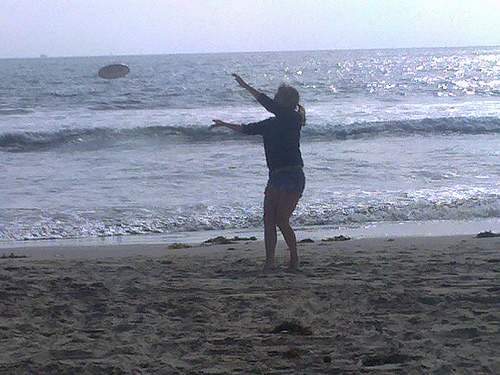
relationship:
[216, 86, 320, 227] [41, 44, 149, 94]
lady to catch frisbee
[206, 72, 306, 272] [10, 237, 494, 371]
lady on beach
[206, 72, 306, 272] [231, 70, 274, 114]
lady with arms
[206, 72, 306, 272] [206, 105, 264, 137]
lady with arms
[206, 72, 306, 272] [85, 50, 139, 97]
lady to catch frisbee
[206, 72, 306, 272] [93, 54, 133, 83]
lady to catch frisbee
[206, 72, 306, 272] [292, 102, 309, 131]
lady with ponytail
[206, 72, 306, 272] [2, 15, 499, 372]
lady on beach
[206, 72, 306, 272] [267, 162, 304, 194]
lady wearing shorts